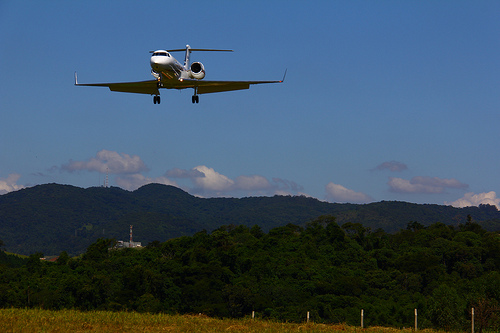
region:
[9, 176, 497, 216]
Mountains in the background of a field.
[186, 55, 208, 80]
A jet engine of an airplane.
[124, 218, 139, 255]
A communications tower near the air field.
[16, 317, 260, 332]
Green grass turning brown.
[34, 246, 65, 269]
A building structure in the background.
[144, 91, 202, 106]
Landing tires on an airplane.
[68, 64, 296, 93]
Total wing span on airplane in flight.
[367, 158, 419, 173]
A gray colored cloud in the air.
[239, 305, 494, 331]
Landing post in an landing field.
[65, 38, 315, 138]
A plane in the sky.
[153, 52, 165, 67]
The nose of the plane.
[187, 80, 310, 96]
The planes left wing.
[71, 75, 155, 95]
The planes right wing.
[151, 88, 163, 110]
The planes right wheel.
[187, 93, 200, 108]
The planes left wheel.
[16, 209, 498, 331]
Green trees and brush.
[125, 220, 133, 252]
Pole in the ground.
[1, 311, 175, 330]
The dry grass.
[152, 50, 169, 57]
The cockpit window.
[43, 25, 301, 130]
This is an airplane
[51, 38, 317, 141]
This is an airplane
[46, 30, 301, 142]
This is an airplane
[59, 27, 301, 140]
This is an airplane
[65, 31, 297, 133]
This is an airplane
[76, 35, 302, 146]
This is an airplane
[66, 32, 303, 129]
This is an airplane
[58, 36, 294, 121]
This is an airplane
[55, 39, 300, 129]
This is an airplane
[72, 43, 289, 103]
A plane in the air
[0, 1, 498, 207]
A blue sky with clouds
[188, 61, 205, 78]
Engine of the plane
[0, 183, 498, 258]
a hill or mountain covered with trees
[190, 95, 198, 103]
Wheel of the plane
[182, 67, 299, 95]
Left wing of plane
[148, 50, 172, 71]
Nose of the plane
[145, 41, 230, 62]
Tail of the plane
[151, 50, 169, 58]
Windshield of the plane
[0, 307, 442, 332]
Grass on the ground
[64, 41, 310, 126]
a large flying aircraft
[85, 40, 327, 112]
a large white plane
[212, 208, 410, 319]
dark green forest trees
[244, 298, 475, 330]
poles on the ground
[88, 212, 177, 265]
a building in the distance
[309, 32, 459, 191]
blue and cloudy day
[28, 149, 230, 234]
green hills in back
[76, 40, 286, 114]
plane has pointed wings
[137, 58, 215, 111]
landing gear is out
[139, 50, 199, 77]
plane has black window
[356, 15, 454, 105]
Large body of blue skies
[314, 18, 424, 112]
Large body of blue skies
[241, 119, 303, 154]
Large body of blue skies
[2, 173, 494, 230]
Mountains in the distance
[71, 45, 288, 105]
A grey plane in the air.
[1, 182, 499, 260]
The most distant strip of trees.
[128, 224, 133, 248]
Orange and white tower.